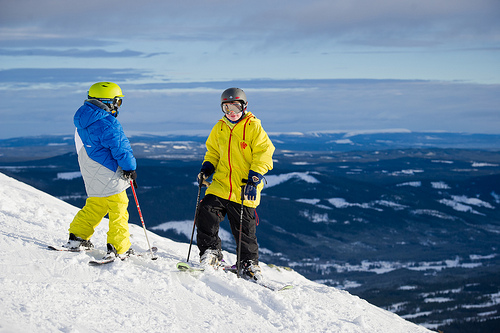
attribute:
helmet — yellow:
[89, 82, 126, 102]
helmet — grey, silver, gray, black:
[219, 90, 250, 110]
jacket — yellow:
[204, 112, 274, 200]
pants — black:
[197, 189, 260, 267]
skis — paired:
[58, 245, 169, 269]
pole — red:
[122, 168, 164, 259]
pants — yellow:
[76, 191, 134, 252]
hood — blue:
[74, 100, 114, 126]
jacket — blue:
[74, 99, 132, 187]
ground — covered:
[5, 181, 426, 332]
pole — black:
[238, 188, 245, 271]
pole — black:
[193, 169, 204, 263]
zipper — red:
[227, 126, 233, 201]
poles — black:
[185, 174, 249, 269]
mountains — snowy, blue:
[10, 131, 499, 177]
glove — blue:
[242, 171, 261, 197]